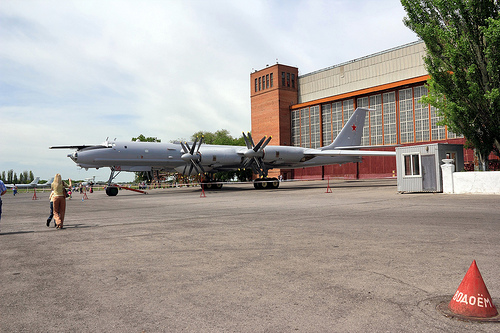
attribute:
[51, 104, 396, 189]
airplane — parked, huge, grey, long, large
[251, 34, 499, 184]
building — red, brick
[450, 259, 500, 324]
cone — orange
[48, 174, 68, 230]
woman — walking, blonde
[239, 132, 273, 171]
propeller — black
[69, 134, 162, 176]
front — small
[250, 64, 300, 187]
tower — brick, red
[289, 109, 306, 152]
window — tall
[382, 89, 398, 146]
window — tall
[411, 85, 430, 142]
window — tall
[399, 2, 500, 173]
tree — growing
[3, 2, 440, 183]
sky — cloudy, blue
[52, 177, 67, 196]
hair — long, blonde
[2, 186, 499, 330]
parking lot — grey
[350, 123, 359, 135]
star — red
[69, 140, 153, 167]
nose — small